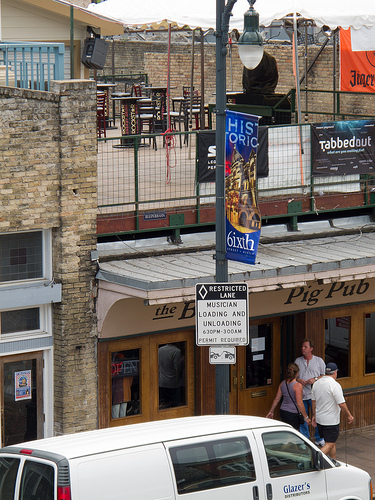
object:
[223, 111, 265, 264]
flag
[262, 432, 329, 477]
window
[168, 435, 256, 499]
window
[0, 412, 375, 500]
van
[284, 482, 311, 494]
company name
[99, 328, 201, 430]
doors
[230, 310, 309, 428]
door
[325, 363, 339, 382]
head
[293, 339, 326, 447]
man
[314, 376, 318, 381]
watch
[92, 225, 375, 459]
business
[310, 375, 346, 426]
shirt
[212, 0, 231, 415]
lamp post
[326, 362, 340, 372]
blue hat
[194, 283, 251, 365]
road sign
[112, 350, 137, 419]
someone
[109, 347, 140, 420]
sign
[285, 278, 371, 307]
restaurant sign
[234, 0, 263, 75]
lamp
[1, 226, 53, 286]
window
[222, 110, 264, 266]
sign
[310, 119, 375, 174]
sign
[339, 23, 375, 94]
sign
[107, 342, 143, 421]
window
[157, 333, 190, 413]
window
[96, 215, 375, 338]
awning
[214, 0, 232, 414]
pole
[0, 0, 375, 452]
building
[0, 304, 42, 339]
window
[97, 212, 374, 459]
pub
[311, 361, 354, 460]
man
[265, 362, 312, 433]
person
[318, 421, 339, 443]
shorts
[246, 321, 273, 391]
window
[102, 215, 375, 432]
front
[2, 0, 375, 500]
photo